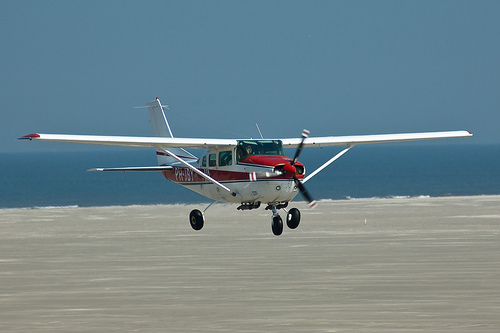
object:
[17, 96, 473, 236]
plane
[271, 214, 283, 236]
tire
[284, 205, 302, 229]
tire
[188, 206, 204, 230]
tire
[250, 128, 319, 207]
propeller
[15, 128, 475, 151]
wing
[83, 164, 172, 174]
wing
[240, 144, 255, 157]
pilot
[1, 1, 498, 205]
sky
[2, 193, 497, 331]
ice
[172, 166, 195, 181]
writing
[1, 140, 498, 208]
water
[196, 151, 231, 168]
windows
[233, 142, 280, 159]
windshield